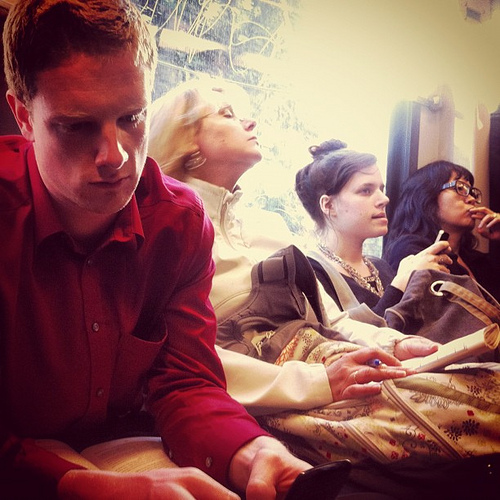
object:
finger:
[349, 365, 405, 384]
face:
[191, 88, 263, 165]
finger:
[341, 380, 384, 400]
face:
[26, 9, 153, 213]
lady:
[148, 75, 500, 483]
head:
[150, 75, 262, 176]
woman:
[387, 160, 499, 285]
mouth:
[462, 206, 477, 215]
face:
[345, 160, 391, 240]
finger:
[173, 459, 245, 500]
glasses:
[441, 177, 486, 204]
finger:
[234, 455, 291, 496]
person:
[0, 1, 317, 498]